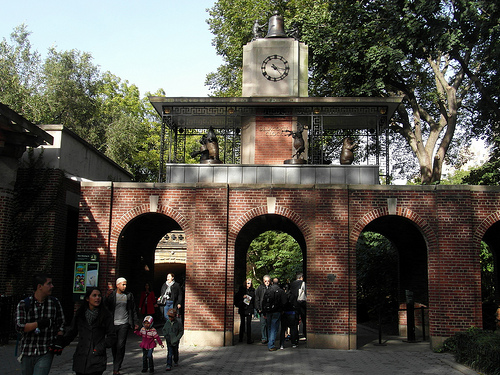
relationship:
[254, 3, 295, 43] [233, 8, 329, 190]
bell on monument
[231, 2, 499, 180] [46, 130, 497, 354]
trees behind wall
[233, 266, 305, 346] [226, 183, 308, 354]
people in archway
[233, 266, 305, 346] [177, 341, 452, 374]
people on path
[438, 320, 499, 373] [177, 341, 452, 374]
bushes by path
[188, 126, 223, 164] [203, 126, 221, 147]
animal of animal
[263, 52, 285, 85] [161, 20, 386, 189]
clock on building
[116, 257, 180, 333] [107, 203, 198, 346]
people in archway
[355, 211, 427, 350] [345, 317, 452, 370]
archway on sidewalk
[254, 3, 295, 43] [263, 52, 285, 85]
bell over clock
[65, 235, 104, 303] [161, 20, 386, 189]
sign on building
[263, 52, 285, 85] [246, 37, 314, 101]
clock on stone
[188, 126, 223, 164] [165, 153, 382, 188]
animal on platform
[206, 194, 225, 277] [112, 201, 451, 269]
brick on arches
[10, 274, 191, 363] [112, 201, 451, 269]
people by arches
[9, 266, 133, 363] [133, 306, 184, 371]
adults with children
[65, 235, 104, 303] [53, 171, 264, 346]
sign on structure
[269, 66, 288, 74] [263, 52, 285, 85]
hands on clock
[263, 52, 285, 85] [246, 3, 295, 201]
clock on tower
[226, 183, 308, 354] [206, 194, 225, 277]
archway of brick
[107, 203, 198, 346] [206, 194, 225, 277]
archway of brick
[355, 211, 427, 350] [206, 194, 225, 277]
archway of brick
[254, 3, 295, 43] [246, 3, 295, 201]
bell on tower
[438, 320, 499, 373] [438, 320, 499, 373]
bushes of bushes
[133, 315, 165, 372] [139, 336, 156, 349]
children in pink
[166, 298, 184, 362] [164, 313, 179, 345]
boy in sweatshirt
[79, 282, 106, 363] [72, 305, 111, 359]
woman in coat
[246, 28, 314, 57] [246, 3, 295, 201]
top of tower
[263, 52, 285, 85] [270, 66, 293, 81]
clock has time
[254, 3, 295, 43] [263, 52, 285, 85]
bell above clock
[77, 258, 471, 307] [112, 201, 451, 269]
row of arches